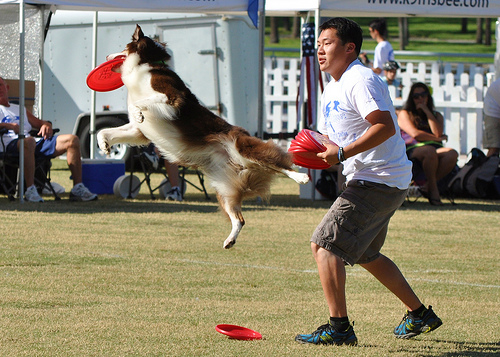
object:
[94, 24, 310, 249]
dog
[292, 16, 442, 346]
man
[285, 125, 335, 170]
frisbees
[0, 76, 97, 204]
man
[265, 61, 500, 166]
fences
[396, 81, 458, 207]
woman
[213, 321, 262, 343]
frisbee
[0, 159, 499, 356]
ground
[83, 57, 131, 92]
frisbee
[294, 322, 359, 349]
shoes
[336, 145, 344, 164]
bracelet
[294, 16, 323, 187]
flag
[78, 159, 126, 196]
cooler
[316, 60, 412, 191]
tshirt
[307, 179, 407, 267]
shorts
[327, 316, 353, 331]
socks